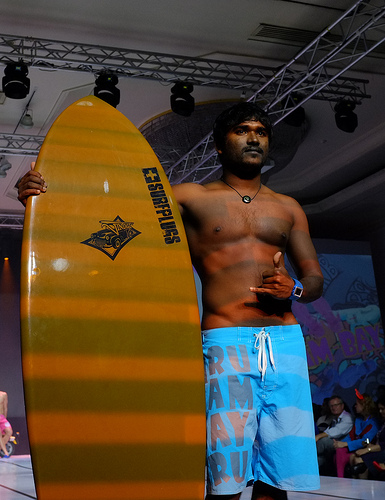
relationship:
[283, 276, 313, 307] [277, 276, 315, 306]
watch on wrist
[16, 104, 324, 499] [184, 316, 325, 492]
man has shorts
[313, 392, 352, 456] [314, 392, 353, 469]
man in man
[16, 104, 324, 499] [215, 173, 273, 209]
man wearing necklace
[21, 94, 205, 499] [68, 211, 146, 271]
surfboard has logo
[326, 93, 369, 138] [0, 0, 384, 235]
light on ceiling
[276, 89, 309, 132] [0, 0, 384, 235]
light on ceiling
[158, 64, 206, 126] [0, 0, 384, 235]
light on ceiling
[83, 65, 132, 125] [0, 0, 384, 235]
light on ceiling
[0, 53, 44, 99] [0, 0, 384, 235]
light on ceiling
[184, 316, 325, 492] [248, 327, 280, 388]
shorts have string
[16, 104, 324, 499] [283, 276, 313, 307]
man wearing watch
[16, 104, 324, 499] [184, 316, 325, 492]
man wearing shorts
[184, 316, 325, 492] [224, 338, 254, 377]
shorts have letter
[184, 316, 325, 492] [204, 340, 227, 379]
shorts have letter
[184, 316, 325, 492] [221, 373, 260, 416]
shorts have letter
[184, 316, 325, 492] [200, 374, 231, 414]
shorts have letter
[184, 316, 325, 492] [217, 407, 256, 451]
shorts have letter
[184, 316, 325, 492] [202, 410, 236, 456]
shorts have letter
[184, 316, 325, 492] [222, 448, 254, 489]
shorts have letter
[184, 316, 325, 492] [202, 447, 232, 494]
shorts have letter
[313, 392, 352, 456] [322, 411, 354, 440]
man wearing shirt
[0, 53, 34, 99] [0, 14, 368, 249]
light attached to ceiling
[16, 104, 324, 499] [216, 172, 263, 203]
man wearing necklace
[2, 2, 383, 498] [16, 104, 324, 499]
picture of man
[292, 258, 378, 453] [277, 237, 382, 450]
graffiti on wall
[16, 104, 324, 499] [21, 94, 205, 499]
man holding surfboard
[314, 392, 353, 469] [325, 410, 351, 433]
man wearing shirt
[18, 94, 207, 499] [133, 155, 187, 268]
surfboard with writing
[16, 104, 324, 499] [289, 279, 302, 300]
man wearing watch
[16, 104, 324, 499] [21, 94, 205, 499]
man with surfboard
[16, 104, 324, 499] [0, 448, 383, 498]
man on stage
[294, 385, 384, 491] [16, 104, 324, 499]
audience watching man